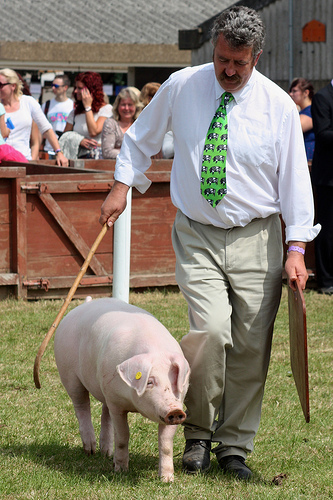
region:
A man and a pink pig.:
[53, 5, 320, 484]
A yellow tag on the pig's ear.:
[133, 369, 142, 378]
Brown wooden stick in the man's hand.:
[32, 190, 127, 389]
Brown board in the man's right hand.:
[285, 253, 310, 423]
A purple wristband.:
[287, 244, 306, 254]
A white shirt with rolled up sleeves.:
[113, 63, 320, 241]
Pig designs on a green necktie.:
[199, 93, 234, 210]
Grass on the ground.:
[0, 285, 332, 499]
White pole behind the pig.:
[112, 184, 131, 303]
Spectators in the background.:
[0, 67, 332, 167]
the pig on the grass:
[53, 298, 190, 483]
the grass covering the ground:
[0, 283, 332, 499]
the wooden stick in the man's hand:
[32, 191, 126, 388]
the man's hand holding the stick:
[98, 188, 127, 226]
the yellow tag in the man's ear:
[136, 372, 140, 379]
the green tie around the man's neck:
[200, 92, 233, 208]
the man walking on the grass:
[98, 5, 320, 480]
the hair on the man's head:
[210, 5, 264, 67]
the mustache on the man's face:
[219, 71, 242, 84]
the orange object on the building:
[301, 18, 325, 42]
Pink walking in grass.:
[3, 285, 332, 499]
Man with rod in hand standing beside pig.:
[32, 3, 331, 488]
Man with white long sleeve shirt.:
[99, 4, 332, 486]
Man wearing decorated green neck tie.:
[99, 7, 322, 496]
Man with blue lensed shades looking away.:
[37, 73, 75, 142]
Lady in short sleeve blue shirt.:
[287, 73, 332, 174]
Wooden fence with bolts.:
[1, 156, 332, 300]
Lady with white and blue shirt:
[0, 67, 70, 171]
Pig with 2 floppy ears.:
[51, 295, 191, 484]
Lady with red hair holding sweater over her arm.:
[58, 69, 112, 166]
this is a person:
[0, 67, 48, 141]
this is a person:
[45, 78, 69, 126]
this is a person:
[113, 80, 141, 132]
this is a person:
[69, 74, 103, 156]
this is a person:
[294, 81, 315, 156]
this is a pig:
[56, 295, 197, 479]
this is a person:
[196, 13, 301, 463]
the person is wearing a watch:
[82, 100, 95, 120]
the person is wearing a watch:
[54, 147, 65, 161]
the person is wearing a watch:
[274, 239, 311, 256]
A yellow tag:
[137, 374, 141, 378]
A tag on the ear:
[136, 373, 140, 378]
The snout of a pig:
[167, 409, 180, 419]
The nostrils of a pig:
[167, 413, 180, 416]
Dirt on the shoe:
[187, 457, 189, 459]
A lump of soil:
[274, 475, 280, 480]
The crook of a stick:
[33, 368, 34, 378]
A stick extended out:
[81, 264, 83, 270]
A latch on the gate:
[22, 185, 39, 186]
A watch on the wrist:
[85, 108, 88, 109]